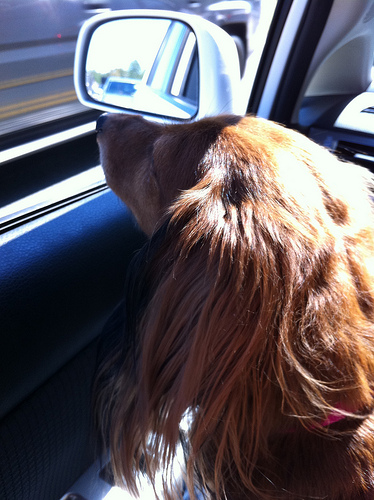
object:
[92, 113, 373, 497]
dog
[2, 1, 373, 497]
car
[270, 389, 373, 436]
colar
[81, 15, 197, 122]
reflection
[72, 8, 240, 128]
mirror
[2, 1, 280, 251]
window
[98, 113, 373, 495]
hair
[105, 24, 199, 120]
door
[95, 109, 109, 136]
nose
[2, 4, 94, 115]
outside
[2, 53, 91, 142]
road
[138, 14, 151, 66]
part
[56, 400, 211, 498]
car seat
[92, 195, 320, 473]
ear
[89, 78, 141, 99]
car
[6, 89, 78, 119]
pole